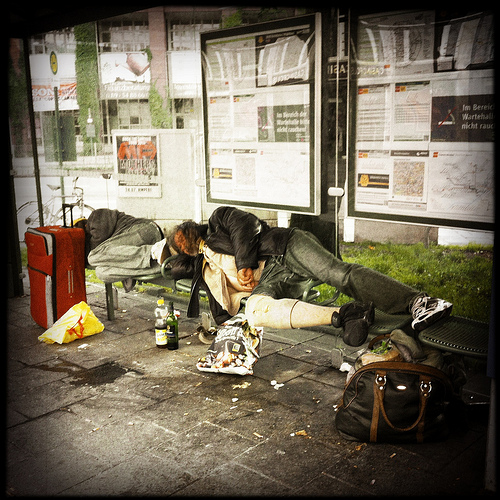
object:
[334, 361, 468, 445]
bag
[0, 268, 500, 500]
sidewalk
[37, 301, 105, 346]
bag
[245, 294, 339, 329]
prostetic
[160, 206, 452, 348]
vagabond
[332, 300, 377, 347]
shoe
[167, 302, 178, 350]
bottle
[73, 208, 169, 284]
hobo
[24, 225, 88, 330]
bag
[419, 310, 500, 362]
bench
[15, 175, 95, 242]
bike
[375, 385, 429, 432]
handle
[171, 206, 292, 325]
jacket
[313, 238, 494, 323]
grass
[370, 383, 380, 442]
trim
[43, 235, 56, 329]
trim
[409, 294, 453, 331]
shoe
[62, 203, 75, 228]
handle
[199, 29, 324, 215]
poster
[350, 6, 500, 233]
poster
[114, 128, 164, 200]
sign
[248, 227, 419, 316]
jeans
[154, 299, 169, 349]
bottle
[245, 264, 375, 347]
leg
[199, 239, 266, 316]
shirt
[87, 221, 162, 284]
pants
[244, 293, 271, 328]
knee